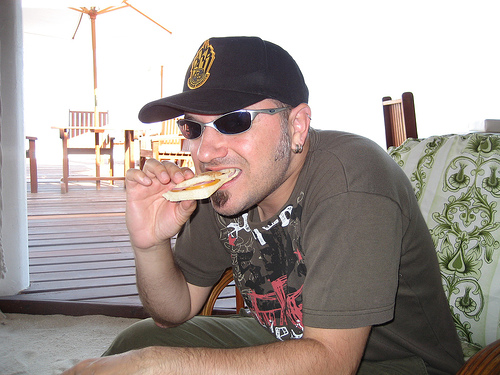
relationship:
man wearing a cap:
[60, 38, 465, 374] [137, 36, 310, 124]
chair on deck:
[51, 106, 116, 192] [5, 177, 259, 313]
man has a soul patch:
[60, 38, 465, 374] [212, 191, 229, 208]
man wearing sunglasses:
[60, 38, 465, 374] [178, 108, 278, 139]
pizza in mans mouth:
[166, 169, 240, 202] [202, 167, 240, 184]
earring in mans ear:
[295, 142, 305, 154] [290, 104, 312, 154]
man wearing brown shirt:
[60, 38, 465, 374] [176, 128, 466, 371]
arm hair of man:
[164, 344, 314, 372] [60, 38, 465, 374]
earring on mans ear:
[295, 142, 305, 154] [290, 104, 312, 154]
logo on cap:
[185, 41, 217, 89] [137, 36, 310, 124]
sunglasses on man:
[178, 108, 278, 139] [60, 38, 465, 374]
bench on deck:
[129, 121, 186, 195] [5, 177, 259, 313]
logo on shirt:
[219, 191, 305, 345] [176, 128, 466, 371]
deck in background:
[5, 177, 259, 313] [0, 1, 497, 311]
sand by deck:
[1, 313, 151, 372] [5, 177, 259, 313]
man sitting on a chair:
[60, 38, 465, 374] [204, 135, 499, 374]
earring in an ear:
[295, 142, 305, 154] [290, 104, 312, 154]